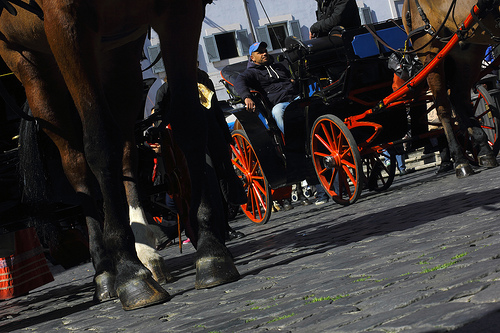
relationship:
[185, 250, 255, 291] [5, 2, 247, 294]
hoof on horse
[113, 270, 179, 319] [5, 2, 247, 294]
hoof on horse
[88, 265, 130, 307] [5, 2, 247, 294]
hoof on horse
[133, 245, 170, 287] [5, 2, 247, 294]
hoof on horse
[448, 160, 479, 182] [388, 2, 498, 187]
hoof on horse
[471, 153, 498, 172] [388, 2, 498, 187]
hoof on horse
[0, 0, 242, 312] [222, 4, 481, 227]
horse pulling carriage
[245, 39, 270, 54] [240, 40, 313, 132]
cap on man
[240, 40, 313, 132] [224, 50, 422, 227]
man in carriage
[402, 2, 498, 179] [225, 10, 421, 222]
horse pulling carriage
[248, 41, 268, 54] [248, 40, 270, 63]
cap on head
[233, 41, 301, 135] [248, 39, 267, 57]
man wearing cap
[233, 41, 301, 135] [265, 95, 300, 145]
man wearing jeans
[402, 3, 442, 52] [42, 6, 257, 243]
straps on horse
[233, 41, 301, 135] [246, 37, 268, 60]
man wearing hat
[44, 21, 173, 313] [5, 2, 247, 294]
leg on horse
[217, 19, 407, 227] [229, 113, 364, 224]
blue wagon with red wheels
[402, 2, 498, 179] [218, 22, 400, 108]
horse pulling carriage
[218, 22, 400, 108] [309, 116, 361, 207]
carriage with wheel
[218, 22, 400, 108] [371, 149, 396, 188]
carriage with wheel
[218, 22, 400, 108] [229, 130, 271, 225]
carriage with red wheels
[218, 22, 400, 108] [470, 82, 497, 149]
carriage with wheel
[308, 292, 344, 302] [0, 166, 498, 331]
grass growing through brick pavement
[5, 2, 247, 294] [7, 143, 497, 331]
horse on pavement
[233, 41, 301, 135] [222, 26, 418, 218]
man riding in carriage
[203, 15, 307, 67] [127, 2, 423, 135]
windows on side of building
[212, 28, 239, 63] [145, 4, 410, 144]
window to a house